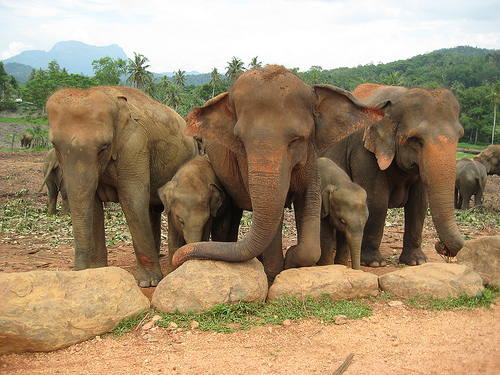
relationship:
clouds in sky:
[159, 8, 239, 55] [72, 0, 488, 116]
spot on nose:
[241, 144, 293, 194] [207, 146, 319, 260]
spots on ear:
[181, 104, 215, 142] [183, 86, 273, 191]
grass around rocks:
[216, 295, 377, 324] [159, 239, 435, 315]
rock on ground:
[270, 268, 380, 298] [276, 297, 425, 364]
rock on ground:
[387, 259, 497, 306] [343, 280, 497, 345]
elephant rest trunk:
[185, 63, 386, 282] [175, 143, 293, 257]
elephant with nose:
[185, 63, 386, 282] [170, 146, 295, 265]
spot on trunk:
[243, 144, 293, 195] [150, 136, 297, 258]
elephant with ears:
[171, 80, 383, 266] [184, 60, 390, 149]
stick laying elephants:
[311, 340, 355, 371] [38, 48, 472, 258]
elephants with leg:
[44, 80, 477, 270] [283, 191, 338, 269]